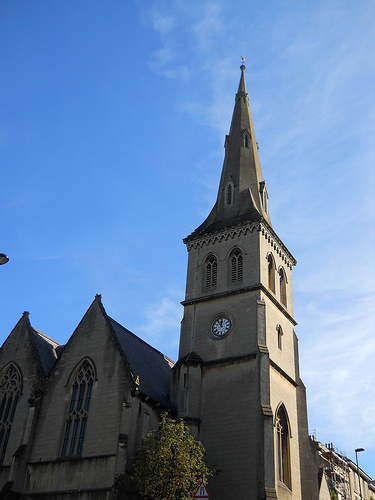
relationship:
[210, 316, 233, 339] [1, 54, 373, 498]
clock on building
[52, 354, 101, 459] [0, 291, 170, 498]
window on side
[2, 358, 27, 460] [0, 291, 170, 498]
window on side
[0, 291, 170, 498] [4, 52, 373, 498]
side of church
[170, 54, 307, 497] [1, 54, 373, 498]
steeple on building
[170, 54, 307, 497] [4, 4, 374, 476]
steeple with sky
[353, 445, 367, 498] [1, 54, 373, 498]
light beside building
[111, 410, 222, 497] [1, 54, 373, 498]
tree in front of building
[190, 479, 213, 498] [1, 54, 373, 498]
sign in front of building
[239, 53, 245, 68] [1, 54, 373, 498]
vane on top of building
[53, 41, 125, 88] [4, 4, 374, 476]
part of sky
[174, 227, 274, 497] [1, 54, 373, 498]
wall of building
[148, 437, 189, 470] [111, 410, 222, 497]
part of tree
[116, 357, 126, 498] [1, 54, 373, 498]
edge of building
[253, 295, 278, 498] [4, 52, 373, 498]
edge of church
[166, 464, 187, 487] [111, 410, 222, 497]
part of tree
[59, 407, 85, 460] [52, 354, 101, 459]
part of window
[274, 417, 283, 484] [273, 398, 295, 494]
part of window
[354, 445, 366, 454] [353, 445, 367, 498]
part of light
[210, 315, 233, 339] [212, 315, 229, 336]
clock with face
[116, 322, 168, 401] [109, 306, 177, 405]
shadow on roof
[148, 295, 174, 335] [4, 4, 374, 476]
clouds in sky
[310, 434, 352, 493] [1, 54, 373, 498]
scaffolding on side of building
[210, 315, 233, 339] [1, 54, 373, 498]
clock on side of building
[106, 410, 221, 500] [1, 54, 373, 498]
tree next to building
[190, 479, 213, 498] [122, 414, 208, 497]
sign next to tree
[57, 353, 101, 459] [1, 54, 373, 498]
window in building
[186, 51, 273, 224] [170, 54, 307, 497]
top of steeple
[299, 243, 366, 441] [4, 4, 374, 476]
cloud in sky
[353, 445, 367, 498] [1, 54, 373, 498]
light next to building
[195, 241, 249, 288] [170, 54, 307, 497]
windows in steeple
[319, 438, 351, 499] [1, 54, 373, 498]
scaffolding on building